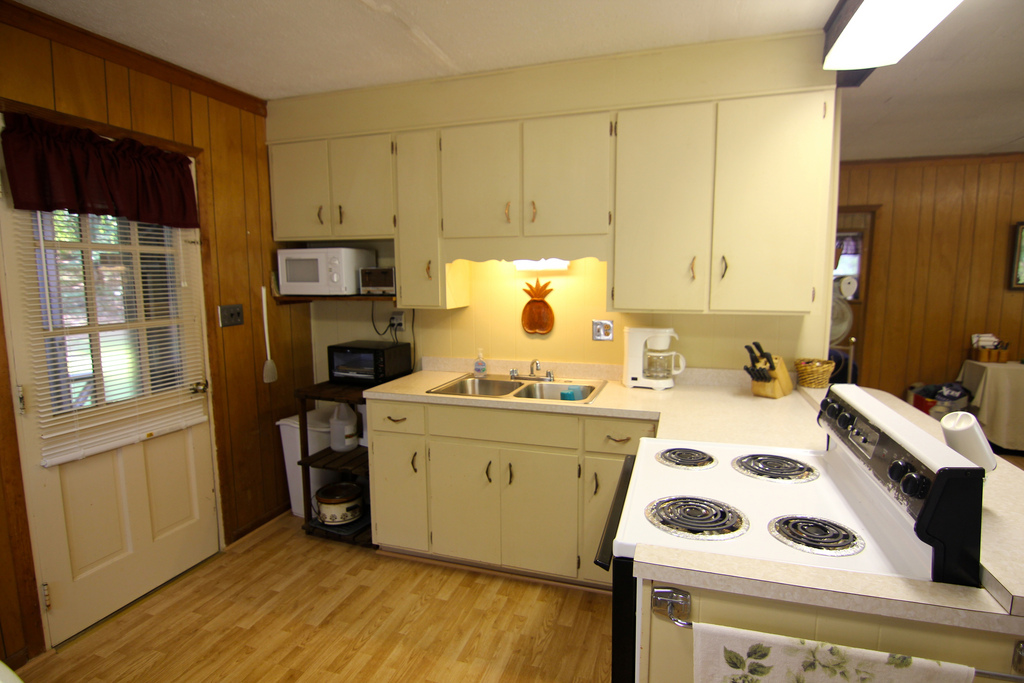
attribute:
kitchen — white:
[50, 74, 947, 660]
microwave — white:
[273, 247, 353, 297]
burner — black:
[733, 446, 818, 479]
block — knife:
[738, 342, 795, 401]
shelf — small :
[267, 292, 414, 561]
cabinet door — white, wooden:
[426, 117, 526, 230]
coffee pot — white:
[615, 321, 693, 393]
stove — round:
[639, 481, 765, 551]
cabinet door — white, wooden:
[706, 88, 825, 322]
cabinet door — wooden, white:
[616, 114, 723, 311]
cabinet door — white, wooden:
[374, 140, 515, 315]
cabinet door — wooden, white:
[266, 121, 333, 232]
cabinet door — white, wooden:
[367, 423, 445, 557]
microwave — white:
[266, 233, 359, 300]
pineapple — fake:
[505, 274, 575, 344]